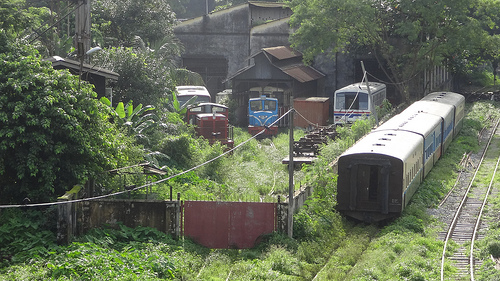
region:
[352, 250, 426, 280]
Grass on the tracks.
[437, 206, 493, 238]
The tracks are grey.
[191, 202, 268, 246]
The fence is red.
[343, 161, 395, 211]
The door is open.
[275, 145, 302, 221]
The pole is wooden.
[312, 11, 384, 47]
The tree is green.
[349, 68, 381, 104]
The pole is leaning.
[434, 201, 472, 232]
Gravel around the tracks.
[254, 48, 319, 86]
The roof is brown.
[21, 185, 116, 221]
The powerline is low.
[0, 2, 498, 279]
Rundown train junk yard.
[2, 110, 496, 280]
Grass that is overgrown and and high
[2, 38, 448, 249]
Fence around the disabled trains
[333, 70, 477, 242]
Four train cars on tracks with grass.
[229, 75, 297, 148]
front of train that is blue, red and white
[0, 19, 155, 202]
Building hidden by the large tree.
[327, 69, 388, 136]
train car that is white with red and blue stripes.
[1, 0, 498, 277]
A rundown train yard with tracks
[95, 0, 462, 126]
An old abandoned train station.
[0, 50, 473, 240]
Electrical lines around the the train yard.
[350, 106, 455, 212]
a train on the side of the track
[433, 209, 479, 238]
a train track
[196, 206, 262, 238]
a fence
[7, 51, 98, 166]
a big gree bush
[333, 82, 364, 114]
a white train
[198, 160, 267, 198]
green bushes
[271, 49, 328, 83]
the roof is brown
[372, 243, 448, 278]
grass on the train tracks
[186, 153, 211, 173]
an electrical line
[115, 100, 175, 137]
green leaves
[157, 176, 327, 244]
red wooden fence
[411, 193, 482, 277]
railroad track with grass overgrowth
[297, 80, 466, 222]
old train cars on a track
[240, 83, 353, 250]
wooden power poles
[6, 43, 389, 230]
electric power lines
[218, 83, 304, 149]
old blue train engine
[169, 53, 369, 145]
old train storage building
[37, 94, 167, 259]
several green shrubs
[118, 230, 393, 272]
patches of green grass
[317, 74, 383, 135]
large window on train car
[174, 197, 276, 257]
the red fence gate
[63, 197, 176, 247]
the cement stone wall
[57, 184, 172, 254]
moss on the wall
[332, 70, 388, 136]
a bus in the yard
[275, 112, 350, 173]
a trailer with items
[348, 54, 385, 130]
the pole tilting over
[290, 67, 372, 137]
the power lines hanging down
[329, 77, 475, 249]
the train in the grass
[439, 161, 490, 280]
the train tracks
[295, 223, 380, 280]
rail lines in the tall grass